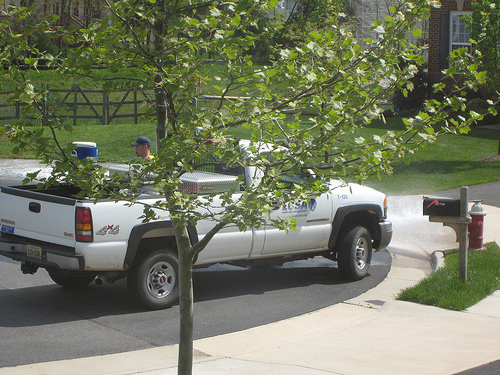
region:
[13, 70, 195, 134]
a rustic wooden fence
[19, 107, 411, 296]
a white pick-up truck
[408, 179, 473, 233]
a black mail box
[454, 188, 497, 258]
a red and white fire hydrant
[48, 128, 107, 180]
a blue drink cooler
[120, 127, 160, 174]
a man in a baseball cap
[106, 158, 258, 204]
a large metal toolbox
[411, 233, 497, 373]
a small patch of grass on sidewalk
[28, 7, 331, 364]
a young tree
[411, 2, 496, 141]
corner of a brick house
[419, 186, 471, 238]
black mailbox with red flag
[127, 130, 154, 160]
man in blue cap by white truck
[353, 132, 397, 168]
flowers and leaves of blooming tree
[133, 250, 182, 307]
part of a back tire on white truck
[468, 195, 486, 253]
red fire hydrant with silver top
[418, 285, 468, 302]
grass growing by the mailbox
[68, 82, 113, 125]
fence behind the white truck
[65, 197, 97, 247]
tail light on white pickup truck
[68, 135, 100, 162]
part of a blue cooler on white truck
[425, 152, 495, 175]
shadows on lawn to the right of the truck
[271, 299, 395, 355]
Gray driveway by a sidewalk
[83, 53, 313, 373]
Tree by a road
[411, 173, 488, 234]
Black mail box on a post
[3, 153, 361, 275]
White truck on a road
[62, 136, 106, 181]
Blue cooler on a truck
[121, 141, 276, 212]
Silver box in a truck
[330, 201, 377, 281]
Black tire on a truck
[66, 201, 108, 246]
Red light on a truck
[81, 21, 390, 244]
Green leaves on a tree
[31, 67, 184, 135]
Wood fence in a yard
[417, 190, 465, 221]
a black mail box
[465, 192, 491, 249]
a red and white mail box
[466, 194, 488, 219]
the white top of a mail box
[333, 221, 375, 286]
a black truck tire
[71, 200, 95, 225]
a red tail light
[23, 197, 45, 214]
a black handle on the truck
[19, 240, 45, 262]
a white license plate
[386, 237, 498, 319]
a patch of green grass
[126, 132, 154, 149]
a blue baseball cap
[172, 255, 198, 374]
the trunk of a tree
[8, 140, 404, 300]
a white truck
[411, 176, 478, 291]
a black mailbox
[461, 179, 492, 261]
a red fire hydrant with a silver top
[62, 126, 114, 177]
a blue water cooler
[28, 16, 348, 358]
a tree with green leaves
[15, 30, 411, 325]
a tree with white flowers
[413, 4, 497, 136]
a brick house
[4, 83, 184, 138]
a wooden fence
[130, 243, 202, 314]
the back right tire of a truck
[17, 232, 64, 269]
the white trucks license plate